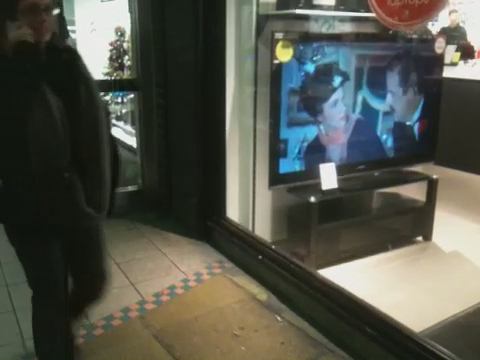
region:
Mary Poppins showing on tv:
[298, 58, 391, 160]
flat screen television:
[269, 33, 437, 178]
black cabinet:
[288, 172, 440, 260]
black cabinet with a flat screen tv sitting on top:
[269, 35, 450, 257]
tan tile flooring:
[111, 236, 207, 263]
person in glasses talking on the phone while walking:
[2, 0, 112, 357]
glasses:
[16, 3, 62, 16]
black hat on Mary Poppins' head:
[297, 60, 351, 101]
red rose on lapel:
[417, 115, 430, 136]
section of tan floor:
[375, 258, 473, 301]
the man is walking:
[7, 7, 170, 338]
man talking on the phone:
[9, 13, 113, 250]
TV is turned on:
[264, 23, 461, 245]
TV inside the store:
[260, 17, 442, 258]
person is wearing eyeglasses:
[18, 1, 114, 35]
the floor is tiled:
[129, 228, 233, 356]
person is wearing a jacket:
[18, 47, 144, 289]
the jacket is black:
[2, 42, 119, 242]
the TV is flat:
[267, 27, 454, 211]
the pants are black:
[20, 234, 124, 325]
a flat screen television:
[267, 22, 451, 196]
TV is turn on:
[265, 25, 448, 186]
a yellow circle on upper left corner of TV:
[265, 29, 449, 183]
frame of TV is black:
[266, 22, 446, 190]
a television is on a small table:
[265, 27, 452, 269]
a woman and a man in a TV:
[274, 37, 434, 166]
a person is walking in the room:
[5, 3, 127, 358]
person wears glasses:
[1, 0, 87, 90]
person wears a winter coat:
[7, 5, 128, 357]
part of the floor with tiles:
[111, 219, 200, 291]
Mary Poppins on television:
[255, 1, 479, 237]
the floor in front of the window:
[150, 220, 318, 359]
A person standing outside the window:
[3, 2, 131, 357]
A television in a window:
[132, 3, 479, 284]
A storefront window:
[223, 3, 478, 359]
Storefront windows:
[68, 9, 460, 356]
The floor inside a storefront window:
[311, 251, 479, 357]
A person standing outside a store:
[5, 3, 119, 359]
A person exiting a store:
[3, 3, 202, 359]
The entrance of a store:
[62, 8, 217, 350]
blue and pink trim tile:
[94, 243, 248, 325]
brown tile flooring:
[137, 298, 291, 359]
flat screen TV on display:
[265, 18, 465, 191]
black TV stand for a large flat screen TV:
[280, 159, 478, 268]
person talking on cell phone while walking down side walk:
[2, 1, 180, 347]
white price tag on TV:
[308, 148, 380, 222]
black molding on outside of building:
[188, 194, 440, 357]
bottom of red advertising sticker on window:
[353, 1, 458, 38]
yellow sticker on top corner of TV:
[254, 14, 347, 120]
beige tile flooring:
[76, 224, 200, 314]